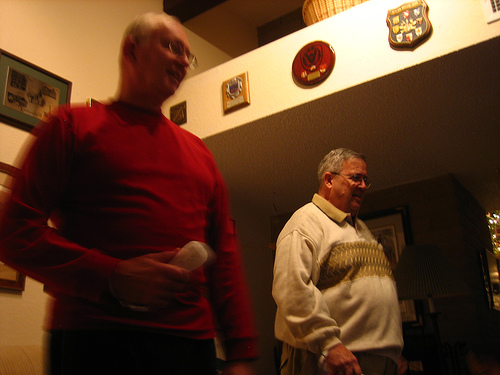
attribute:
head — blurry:
[113, 12, 196, 104]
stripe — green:
[325, 246, 396, 280]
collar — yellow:
[312, 192, 351, 222]